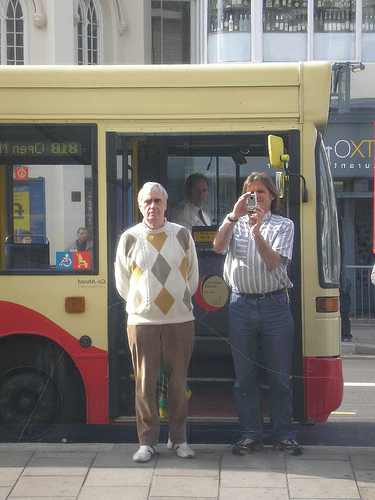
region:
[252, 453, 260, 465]
part of a pavement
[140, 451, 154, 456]
part of a shoe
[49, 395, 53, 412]
part of a wheel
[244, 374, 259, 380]
part of a knee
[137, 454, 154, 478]
part of a shoe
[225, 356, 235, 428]
part of a stair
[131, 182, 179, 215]
man has white hair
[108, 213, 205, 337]
man has argyle sweater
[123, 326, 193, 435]
man has brown pants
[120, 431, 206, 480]
black and white shoes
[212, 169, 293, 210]
man has brown hair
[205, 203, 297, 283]
grey and white shirt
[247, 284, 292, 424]
man has blue pants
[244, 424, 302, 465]
man has black shoes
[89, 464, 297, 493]
grey sidewalk near men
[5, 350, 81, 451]
black tire on bus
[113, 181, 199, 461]
Man in a white sweater near a bus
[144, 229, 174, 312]
Diamond pattern on a sweater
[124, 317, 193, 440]
Brown slacks on a man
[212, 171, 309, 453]
Man in a striped shirt with a camera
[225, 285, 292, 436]
Blue jeans on a man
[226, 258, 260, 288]
Striped pattern on a man's shirt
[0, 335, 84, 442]
Wheel on the bus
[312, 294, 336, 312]
Turning signal on a bus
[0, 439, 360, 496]
Concrete slabs on the footpath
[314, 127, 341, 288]
Front windshield on a bus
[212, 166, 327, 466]
man with a camera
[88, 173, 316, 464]
men standing in front of bus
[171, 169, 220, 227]
driver of a bus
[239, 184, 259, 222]
camera in man's hand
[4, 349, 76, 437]
tire on a bus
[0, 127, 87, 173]
route of a bus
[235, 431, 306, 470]
sneakers on a man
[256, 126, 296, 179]
sideview mirror on bus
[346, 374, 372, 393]
white line painted in street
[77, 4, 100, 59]
windows of a building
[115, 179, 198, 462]
a man is standing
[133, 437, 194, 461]
the shoes are white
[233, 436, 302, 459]
black and gray shoes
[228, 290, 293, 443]
the jeans are blue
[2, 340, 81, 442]
the tire is black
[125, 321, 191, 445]
the pants are brown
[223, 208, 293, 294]
the shirt is striped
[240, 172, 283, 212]
man has long hair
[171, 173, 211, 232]
guy driving the bus